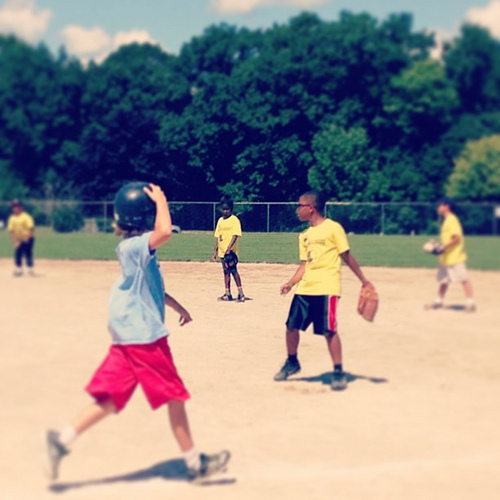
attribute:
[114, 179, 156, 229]
helmet — black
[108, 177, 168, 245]
helmet — black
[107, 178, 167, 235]
helmet — black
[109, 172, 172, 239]
helmet — black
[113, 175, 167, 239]
helmet — black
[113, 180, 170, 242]
helmet — black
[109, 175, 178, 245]
helmet — black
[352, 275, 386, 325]
baseball mitt — brown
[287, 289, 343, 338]
shorts — black, red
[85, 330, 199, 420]
shorts — red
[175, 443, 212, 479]
socks — white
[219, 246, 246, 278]
shorts — black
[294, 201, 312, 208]
eyeglasses — black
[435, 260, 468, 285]
shorts — khaki